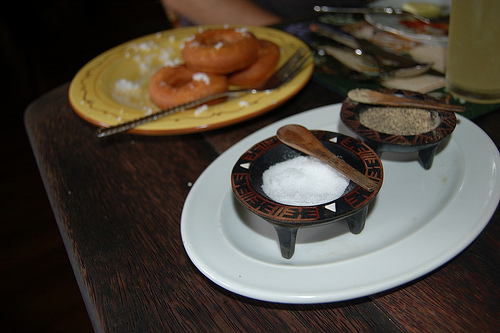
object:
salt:
[256, 151, 352, 210]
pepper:
[358, 105, 442, 135]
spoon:
[346, 86, 468, 114]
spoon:
[276, 123, 383, 198]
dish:
[179, 95, 500, 306]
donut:
[184, 28, 256, 77]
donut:
[149, 64, 224, 112]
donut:
[225, 38, 284, 86]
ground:
[0, 120, 33, 175]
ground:
[0, 217, 88, 333]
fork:
[93, 47, 316, 138]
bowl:
[239, 126, 386, 259]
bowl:
[339, 88, 459, 169]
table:
[23, 89, 500, 333]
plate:
[64, 23, 312, 133]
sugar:
[191, 73, 211, 87]